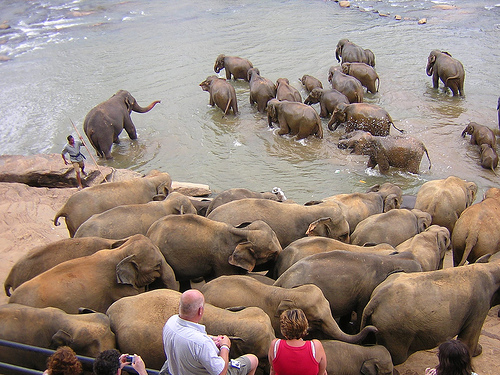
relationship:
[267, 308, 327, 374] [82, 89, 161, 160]
woman watching elephant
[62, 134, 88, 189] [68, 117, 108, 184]
man carrying stick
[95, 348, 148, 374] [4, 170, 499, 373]
person photographing elephants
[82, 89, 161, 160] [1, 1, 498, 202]
elephant in water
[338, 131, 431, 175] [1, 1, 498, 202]
elephant spraying in water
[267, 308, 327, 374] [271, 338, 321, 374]
woman wearing tank top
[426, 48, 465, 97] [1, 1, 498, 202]
elephant in water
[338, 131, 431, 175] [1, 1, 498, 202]
elephant in water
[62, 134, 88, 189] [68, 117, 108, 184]
man holding stick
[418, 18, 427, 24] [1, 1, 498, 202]
rock in water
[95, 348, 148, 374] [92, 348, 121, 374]
person has black hair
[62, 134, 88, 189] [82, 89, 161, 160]
man by elephant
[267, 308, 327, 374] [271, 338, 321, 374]
woman in tank top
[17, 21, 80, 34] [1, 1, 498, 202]
wave on water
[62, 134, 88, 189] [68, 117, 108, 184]
man with stick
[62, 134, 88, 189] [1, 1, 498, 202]
man near water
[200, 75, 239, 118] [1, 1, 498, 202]
elephant in water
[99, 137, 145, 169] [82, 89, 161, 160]
shadow of elephant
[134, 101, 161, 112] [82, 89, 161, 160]
trunk on elephant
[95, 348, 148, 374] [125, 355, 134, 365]
person holding camera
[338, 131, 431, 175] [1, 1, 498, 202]
elephant spraying water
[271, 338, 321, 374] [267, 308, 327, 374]
tank top on woman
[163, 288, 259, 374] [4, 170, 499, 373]
man watching elephants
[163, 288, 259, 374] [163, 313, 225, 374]
man in shirt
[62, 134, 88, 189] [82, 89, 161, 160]
man near elephant